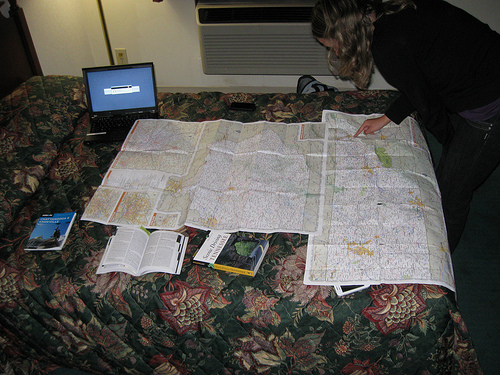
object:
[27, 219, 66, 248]
travel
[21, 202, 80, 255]
book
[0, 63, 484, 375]
bed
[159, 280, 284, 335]
quilt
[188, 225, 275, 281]
guidebook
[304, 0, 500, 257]
female's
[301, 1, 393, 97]
hair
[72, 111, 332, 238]
map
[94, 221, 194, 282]
book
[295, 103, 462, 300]
map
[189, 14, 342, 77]
unit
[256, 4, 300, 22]
air conditioning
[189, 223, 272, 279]
books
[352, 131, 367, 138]
pointing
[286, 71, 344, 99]
backpack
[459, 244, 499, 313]
ground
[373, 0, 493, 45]
top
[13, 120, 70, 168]
flower drawing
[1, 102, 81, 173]
comforter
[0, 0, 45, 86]
headboard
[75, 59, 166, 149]
computers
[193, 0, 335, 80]
air conditioner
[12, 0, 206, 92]
wall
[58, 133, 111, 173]
bed spread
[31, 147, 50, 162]
flower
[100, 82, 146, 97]
design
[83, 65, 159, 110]
screen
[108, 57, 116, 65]
part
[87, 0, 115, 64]
lamp post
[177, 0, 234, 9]
window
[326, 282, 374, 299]
brochure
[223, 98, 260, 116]
cell phone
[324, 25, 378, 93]
brown hair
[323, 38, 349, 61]
face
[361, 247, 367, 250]
markings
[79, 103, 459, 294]
two maps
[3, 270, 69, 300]
bedspread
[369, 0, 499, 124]
black sweater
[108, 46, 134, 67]
electrical outlet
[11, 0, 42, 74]
edge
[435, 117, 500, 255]
jeans